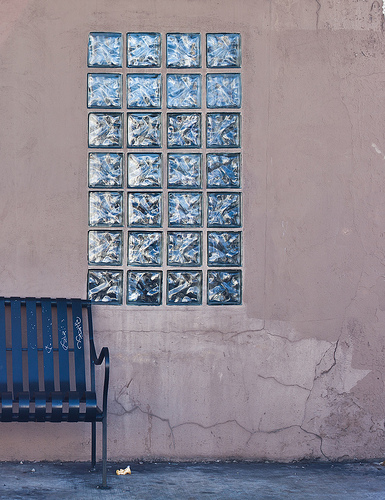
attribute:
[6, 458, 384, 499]
ground — black, cement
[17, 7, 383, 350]
wall — pink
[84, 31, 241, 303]
window — square, blue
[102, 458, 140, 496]
piece litter — small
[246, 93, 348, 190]
wall — pink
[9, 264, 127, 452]
bench — blue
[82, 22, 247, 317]
window — square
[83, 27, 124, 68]
windows — small, square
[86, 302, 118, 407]
armrest railing — metal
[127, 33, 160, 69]
window — square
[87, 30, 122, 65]
window — square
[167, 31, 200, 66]
window — square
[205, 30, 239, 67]
window — square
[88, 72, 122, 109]
window — square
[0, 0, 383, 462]
wall — stone, tan, cement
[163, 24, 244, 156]
window — blue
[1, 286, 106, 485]
bench — metal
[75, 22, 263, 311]
decorations — square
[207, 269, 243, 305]
window — square, glassy